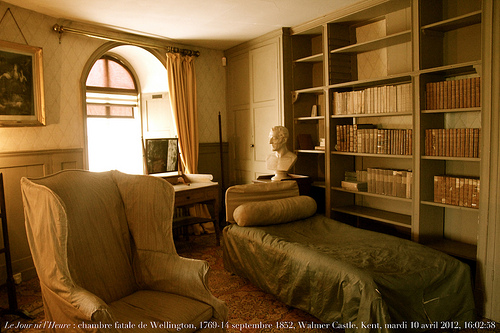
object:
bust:
[265, 125, 298, 173]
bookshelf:
[288, 0, 492, 264]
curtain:
[164, 52, 216, 236]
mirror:
[143, 137, 183, 175]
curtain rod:
[50, 23, 202, 57]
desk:
[172, 181, 222, 246]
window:
[85, 44, 185, 175]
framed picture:
[0, 39, 47, 128]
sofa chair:
[220, 180, 477, 333]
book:
[341, 180, 368, 188]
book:
[341, 187, 367, 192]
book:
[366, 167, 372, 193]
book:
[371, 168, 376, 194]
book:
[375, 170, 379, 194]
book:
[379, 170, 384, 195]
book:
[383, 170, 388, 196]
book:
[387, 170, 392, 196]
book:
[392, 170, 397, 196]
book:
[397, 171, 402, 198]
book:
[401, 171, 406, 199]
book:
[406, 171, 411, 198]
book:
[410, 171, 413, 199]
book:
[296, 133, 314, 149]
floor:
[0, 231, 500, 333]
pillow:
[233, 195, 318, 228]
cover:
[221, 215, 474, 332]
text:
[4, 320, 495, 330]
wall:
[0, 0, 230, 290]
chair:
[18, 169, 230, 333]